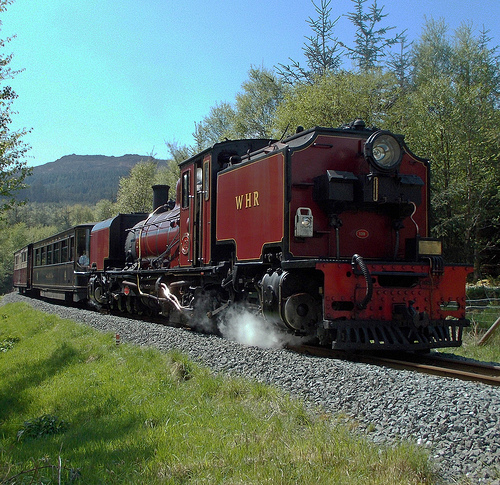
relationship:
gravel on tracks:
[3, 287, 480, 479] [3, 282, 498, 401]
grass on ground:
[35, 369, 245, 461] [4, 292, 498, 482]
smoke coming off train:
[219, 302, 284, 354] [74, 74, 464, 396]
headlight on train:
[365, 129, 404, 173] [65, 132, 487, 356]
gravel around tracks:
[3, 287, 480, 479] [365, 337, 498, 389]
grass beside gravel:
[0, 301, 500, 485] [350, 357, 499, 477]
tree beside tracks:
[391, 48, 498, 238] [3, 282, 498, 401]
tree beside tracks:
[269, 72, 397, 146] [3, 282, 498, 401]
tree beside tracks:
[228, 66, 297, 147] [3, 282, 498, 401]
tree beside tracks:
[184, 101, 234, 151] [3, 282, 498, 401]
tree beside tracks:
[449, 24, 499, 284] [3, 282, 498, 401]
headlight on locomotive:
[365, 128, 408, 173] [9, 113, 471, 351]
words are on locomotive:
[235, 191, 260, 211] [9, 113, 471, 351]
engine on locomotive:
[111, 215, 205, 331] [111, 173, 238, 350]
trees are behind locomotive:
[421, 42, 481, 102] [116, 111, 473, 359]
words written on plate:
[232, 189, 261, 209] [210, 147, 286, 259]